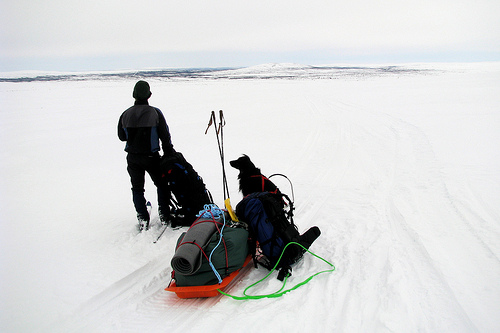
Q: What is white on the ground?
A: Snow.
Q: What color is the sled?
A: Orange.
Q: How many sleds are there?
A: One.